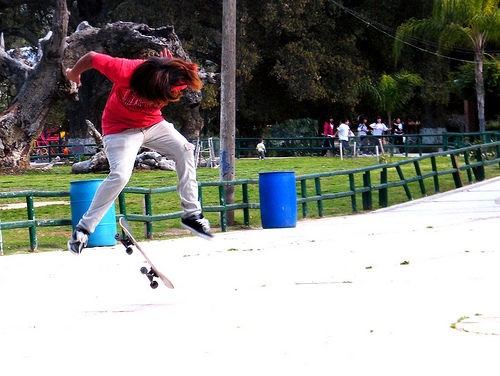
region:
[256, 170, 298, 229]
A small water can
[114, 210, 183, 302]
A skate board in the air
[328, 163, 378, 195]
A fence in the photo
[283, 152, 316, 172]
A green in the photo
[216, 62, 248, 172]
A pole in the photo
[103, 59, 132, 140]
A red t-shirt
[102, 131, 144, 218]
Gray pants in the photo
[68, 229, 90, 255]
Black shoe in the photo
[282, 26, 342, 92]
A tree in the photo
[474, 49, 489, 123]
A tree trunk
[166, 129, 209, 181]
knee on pants is torn out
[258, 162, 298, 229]
jewel toned blue trash can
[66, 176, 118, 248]
lighter blue refuse container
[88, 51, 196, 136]
red short sleeved shirt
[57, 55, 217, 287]
skate boarder jumps in with board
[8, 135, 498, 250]
green split rail fence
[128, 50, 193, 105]
skate boarder's hair is flying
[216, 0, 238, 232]
a utility pole with blue paint spot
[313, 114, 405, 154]
group of people gathered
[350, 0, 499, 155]
two younger weeping trees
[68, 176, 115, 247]
lighter blue trash can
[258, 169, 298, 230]
darker blue trash can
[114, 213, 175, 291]
black wooden skateboard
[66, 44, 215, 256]
young skateboarder in a red shirt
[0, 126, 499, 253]
green wooden fencing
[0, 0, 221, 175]
large gnarled dead tree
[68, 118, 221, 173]
huge branch on the ground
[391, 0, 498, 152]
tall palm tree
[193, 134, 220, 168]
short metal ladder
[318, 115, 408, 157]
group of people standing near the cars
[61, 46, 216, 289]
a skateboarder performing a trick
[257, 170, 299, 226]
a blue garbage can against a fence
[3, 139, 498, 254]
a small green metal fence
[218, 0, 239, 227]
a wooden pole in a park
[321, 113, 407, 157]
people walking in a park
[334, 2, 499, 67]
telephone wires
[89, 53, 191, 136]
a young woman wearing a pink shirt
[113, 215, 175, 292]
a skateboard flying in the air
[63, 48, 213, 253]
a young woman with her feet above the ground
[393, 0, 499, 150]
a green lush tree in a park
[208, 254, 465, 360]
The ground is made cement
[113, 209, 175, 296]
The skateboard is in the air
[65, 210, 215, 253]
The shoes on the boy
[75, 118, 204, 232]
The man has on khaki pants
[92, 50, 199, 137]
The boy has on a red shirt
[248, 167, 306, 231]
A blue trash can in the park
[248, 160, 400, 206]
The grass in the park is green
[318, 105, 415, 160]
A group of people in the park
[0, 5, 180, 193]
The tree trunk is brown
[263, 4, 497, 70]
The leaves on the tree are green